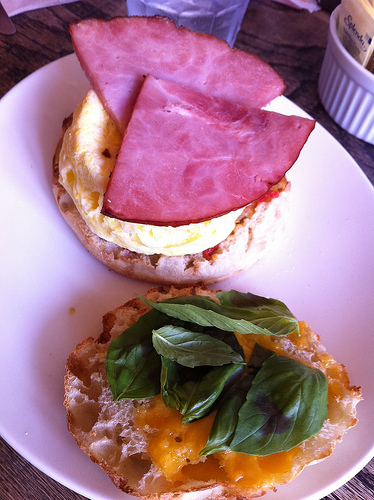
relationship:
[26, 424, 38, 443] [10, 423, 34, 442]
crumb on plate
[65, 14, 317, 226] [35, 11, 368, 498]
ham meat on sandwich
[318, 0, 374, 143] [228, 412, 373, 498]
bowl on table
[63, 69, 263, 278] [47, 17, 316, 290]
bottom of english muffin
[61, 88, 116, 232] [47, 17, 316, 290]
egg on english muffin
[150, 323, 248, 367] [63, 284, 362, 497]
leaf on sandwich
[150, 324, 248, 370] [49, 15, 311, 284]
leaf on sandwich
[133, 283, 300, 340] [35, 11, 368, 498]
leaf on sandwich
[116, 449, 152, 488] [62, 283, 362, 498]
whole in bagel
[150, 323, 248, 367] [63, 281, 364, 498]
leaf on english muffin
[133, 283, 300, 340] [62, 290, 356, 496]
leaf on muffin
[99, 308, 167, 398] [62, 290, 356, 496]
spinach leaf on muffin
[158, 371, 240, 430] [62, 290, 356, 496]
spinach leaf on muffin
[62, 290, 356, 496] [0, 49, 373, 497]
muffin on plate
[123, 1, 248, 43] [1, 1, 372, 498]
drinking glass on table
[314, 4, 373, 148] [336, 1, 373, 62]
bowl holding sugar packets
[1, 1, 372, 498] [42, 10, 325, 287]
table under sandwich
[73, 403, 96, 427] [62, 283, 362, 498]
hole in a bagel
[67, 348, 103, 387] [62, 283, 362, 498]
hole in a bagel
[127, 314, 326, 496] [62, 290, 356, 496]
cheese on muffin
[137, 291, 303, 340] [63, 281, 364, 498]
leaf on english muffin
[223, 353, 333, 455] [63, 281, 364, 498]
leaf on english muffin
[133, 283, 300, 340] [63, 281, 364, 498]
leaf on english muffin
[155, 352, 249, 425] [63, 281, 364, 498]
leaf on english muffin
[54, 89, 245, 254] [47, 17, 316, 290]
egg on english muffin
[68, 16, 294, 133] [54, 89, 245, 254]
ham on egg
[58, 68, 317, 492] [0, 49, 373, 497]
english muffins on plate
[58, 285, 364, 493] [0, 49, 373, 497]
english muffins on plate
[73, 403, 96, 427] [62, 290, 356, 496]
hole in muffin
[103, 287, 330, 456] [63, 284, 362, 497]
leaves on sandwich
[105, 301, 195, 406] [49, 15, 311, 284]
leaf on sandwich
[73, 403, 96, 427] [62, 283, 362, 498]
hole in bagel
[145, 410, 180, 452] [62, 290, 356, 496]
jam on muffin